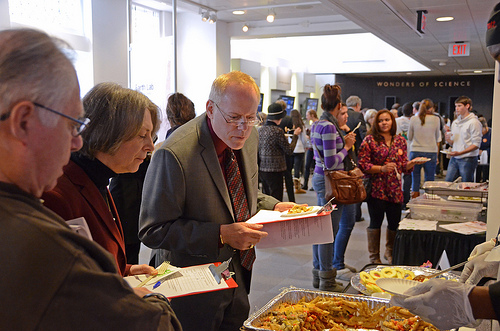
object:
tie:
[222, 148, 257, 271]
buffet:
[240, 265, 470, 331]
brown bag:
[324, 167, 367, 205]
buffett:
[169, 181, 485, 327]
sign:
[376, 81, 471, 88]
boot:
[366, 227, 382, 264]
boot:
[384, 225, 397, 264]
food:
[251, 296, 436, 331]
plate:
[281, 205, 320, 215]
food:
[287, 204, 314, 214]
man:
[1, 28, 182, 331]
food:
[415, 157, 430, 161]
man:
[444, 96, 482, 183]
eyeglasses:
[214, 102, 263, 126]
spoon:
[351, 121, 361, 132]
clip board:
[245, 197, 337, 225]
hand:
[391, 279, 479, 330]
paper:
[121, 263, 229, 298]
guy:
[138, 70, 308, 331]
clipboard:
[123, 257, 238, 298]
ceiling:
[212, 0, 496, 72]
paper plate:
[375, 278, 422, 297]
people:
[310, 83, 356, 292]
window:
[124, 0, 173, 102]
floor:
[251, 178, 394, 299]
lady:
[42, 81, 163, 276]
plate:
[413, 158, 431, 162]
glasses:
[0, 99, 92, 133]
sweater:
[310, 120, 349, 176]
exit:
[448, 43, 471, 57]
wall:
[333, 72, 491, 116]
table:
[370, 277, 429, 301]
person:
[356, 109, 430, 265]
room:
[0, 0, 500, 331]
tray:
[242, 287, 459, 330]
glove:
[390, 279, 482, 330]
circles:
[359, 267, 415, 291]